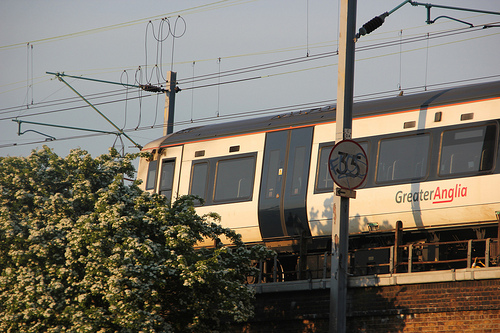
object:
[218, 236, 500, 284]
tracks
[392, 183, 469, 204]
writing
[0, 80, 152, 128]
wires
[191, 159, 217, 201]
window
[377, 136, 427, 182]
window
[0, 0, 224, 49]
power lines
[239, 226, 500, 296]
bridge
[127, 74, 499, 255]
train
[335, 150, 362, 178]
number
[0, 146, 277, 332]
bush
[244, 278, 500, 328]
wall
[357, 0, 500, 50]
wireline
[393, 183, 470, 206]
sign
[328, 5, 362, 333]
pole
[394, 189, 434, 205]
word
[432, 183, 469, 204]
word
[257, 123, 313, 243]
door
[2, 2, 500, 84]
sky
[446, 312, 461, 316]
brick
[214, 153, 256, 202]
window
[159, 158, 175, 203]
window